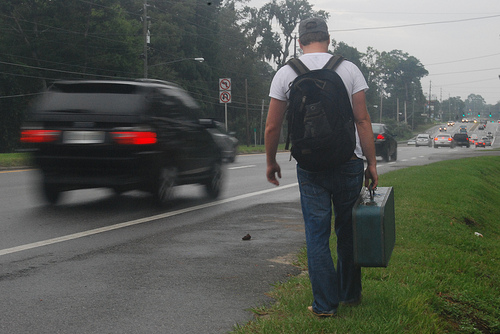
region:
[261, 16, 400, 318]
man walking on side of the freeway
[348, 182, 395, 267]
green suitcase in mans hand walking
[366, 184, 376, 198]
handle in hand of the man suitcase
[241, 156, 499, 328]
grassy area man walking on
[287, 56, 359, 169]
back pack on back of man walking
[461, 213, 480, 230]
hole in the grass where the man is walking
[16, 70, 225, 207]
black car on the highway where man is walking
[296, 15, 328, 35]
hat on the head of the man walking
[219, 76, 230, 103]
road sign of the highway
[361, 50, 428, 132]
trees on the side of the highway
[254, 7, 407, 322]
A man in the foreground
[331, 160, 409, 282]
Man is carrying a green case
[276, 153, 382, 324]
Man is wearing blue jeans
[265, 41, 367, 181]
Man is wearing a backpack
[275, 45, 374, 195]
The backpack is black in color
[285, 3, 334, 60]
Man is wearing a cap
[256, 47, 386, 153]
Man is wearing a white T-shirt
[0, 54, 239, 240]
A black car driving by the man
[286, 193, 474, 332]
Man is walking on the grass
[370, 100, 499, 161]
Cars in the background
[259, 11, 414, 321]
The man is carrying a suitcase.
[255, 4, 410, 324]
The man is wearing a backpack.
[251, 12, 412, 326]
The man is a cap.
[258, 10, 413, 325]
The man is wearing a shirt.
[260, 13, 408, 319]
The man is wearing pants.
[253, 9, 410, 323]
The man's shirt is white.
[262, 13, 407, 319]
The man's shirt has short sleeves.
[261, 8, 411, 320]
The man's pants are blue.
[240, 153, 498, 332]
The grass is green.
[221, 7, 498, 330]
The man is standing on the grass.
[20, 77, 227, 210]
A black SUV in motion.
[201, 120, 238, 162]
A silver vehicle in motion.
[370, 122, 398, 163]
A black car with its brake lights on.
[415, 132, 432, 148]
A Toyota Prius in the road.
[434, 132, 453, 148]
A vehicle stopped in traffic.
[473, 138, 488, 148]
A vehicle stopped in traffic.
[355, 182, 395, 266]
An old-fashioned suitcase.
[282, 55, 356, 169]
A backpack being worn by a man.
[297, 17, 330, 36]
A cap being worn by a man.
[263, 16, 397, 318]
A man walking on the side of the road.